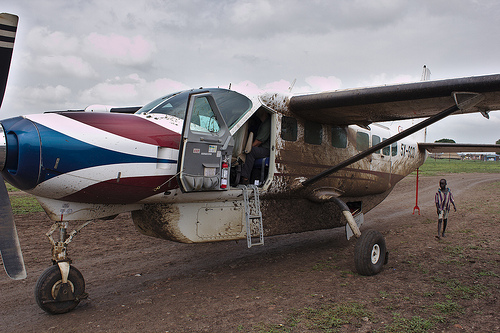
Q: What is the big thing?
A: Plane.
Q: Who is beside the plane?
A: A man.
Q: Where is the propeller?
A: In front of plane.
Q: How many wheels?
A: 2.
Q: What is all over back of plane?
A: Mud.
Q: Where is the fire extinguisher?
A: Door of plane.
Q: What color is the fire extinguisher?
A: Red.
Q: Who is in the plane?
A: A person.